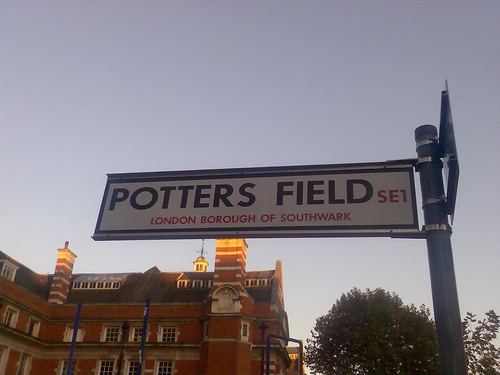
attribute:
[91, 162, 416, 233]
sign — white, green, whitewhite, vwhite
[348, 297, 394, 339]
tree — green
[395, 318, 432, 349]
leaves — green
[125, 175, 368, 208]
letters — black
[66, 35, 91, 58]
sky — blue, vblue